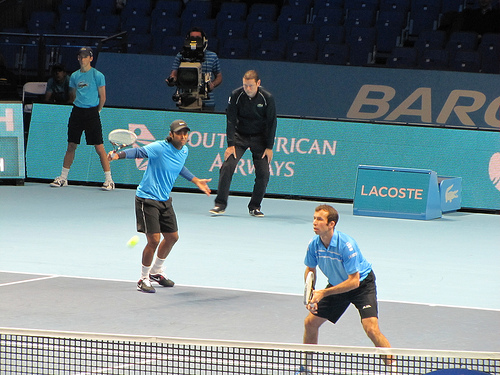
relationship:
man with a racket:
[104, 118, 213, 292] [108, 123, 137, 156]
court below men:
[1, 180, 500, 370] [104, 117, 400, 374]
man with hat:
[104, 118, 213, 292] [168, 117, 194, 137]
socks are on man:
[136, 271, 177, 292] [104, 118, 213, 292]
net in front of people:
[3, 327, 500, 372] [104, 117, 400, 374]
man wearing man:
[209, 69, 281, 219] [209, 69, 281, 219]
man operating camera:
[167, 29, 226, 111] [172, 34, 214, 111]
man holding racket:
[104, 118, 213, 292] [108, 123, 137, 156]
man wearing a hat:
[104, 118, 213, 292] [168, 117, 194, 137]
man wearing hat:
[104, 118, 213, 292] [168, 117, 194, 137]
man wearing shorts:
[104, 118, 213, 292] [131, 193, 183, 233]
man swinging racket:
[104, 118, 213, 292] [108, 123, 137, 156]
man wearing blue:
[290, 202, 405, 374] [302, 233, 373, 287]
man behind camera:
[167, 29, 226, 111] [172, 34, 214, 111]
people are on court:
[104, 117, 400, 374] [1, 180, 500, 370]